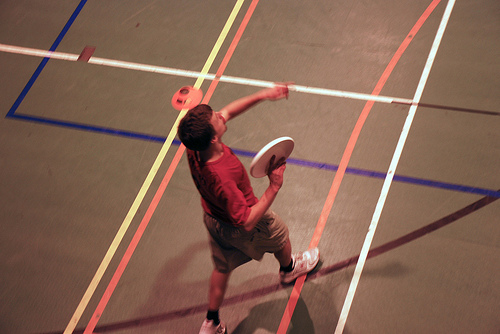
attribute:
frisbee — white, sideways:
[247, 136, 297, 180]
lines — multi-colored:
[372, 10, 449, 88]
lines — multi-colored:
[287, 94, 440, 266]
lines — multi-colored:
[181, 8, 268, 105]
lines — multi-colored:
[12, 14, 154, 164]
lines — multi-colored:
[51, 109, 187, 331]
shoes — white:
[272, 246, 325, 288]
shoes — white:
[180, 312, 235, 332]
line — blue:
[26, 1, 449, 255]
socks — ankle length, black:
[188, 253, 339, 331]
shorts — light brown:
[188, 203, 312, 303]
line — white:
[333, 0, 456, 332]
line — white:
[0, 42, 418, 104]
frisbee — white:
[248, 135, 300, 191]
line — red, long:
[272, 2, 428, 332]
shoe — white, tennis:
[277, 246, 323, 289]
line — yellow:
[329, 106, 413, 331]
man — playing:
[96, 64, 386, 332]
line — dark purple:
[400, 165, 451, 191]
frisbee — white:
[240, 135, 292, 186]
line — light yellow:
[116, 187, 148, 207]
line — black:
[390, 211, 464, 240]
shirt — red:
[184, 136, 264, 226]